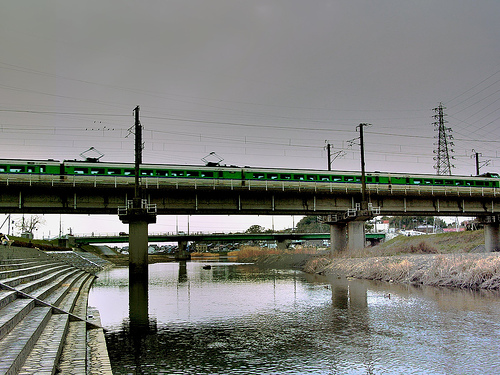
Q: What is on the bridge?
A: Train.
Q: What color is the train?
A: Green.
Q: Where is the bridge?
A: Over the river.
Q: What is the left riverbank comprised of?
A: Stone steps.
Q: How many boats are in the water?
A: None.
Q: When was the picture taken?
A: Daytime.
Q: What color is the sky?
A: Gray.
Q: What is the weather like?
A: Overcast.